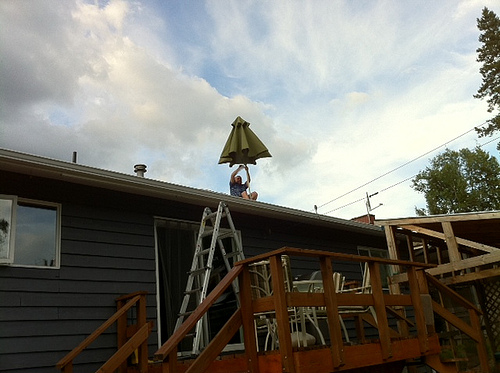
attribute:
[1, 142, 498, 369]
building — grey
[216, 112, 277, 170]
umbrella — green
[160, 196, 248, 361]
ladder — grey, white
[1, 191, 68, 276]
window — white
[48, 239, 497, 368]
deck — brown, wooden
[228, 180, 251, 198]
shirt — blue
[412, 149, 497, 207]
tree — green